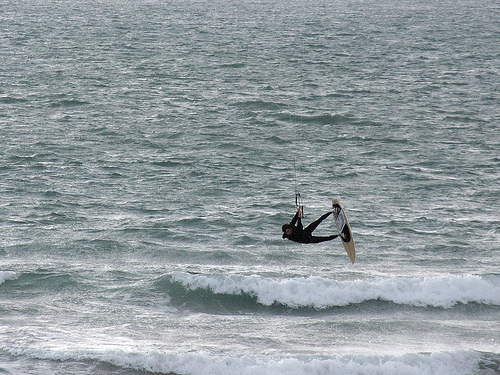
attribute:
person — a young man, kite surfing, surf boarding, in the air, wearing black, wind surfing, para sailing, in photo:
[281, 206, 348, 243]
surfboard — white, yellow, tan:
[331, 198, 357, 265]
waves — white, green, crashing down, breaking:
[5, 175, 495, 370]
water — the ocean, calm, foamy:
[1, 2, 496, 369]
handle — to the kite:
[294, 190, 306, 220]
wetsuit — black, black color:
[283, 215, 338, 244]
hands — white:
[296, 207, 303, 221]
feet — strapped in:
[331, 207, 347, 240]